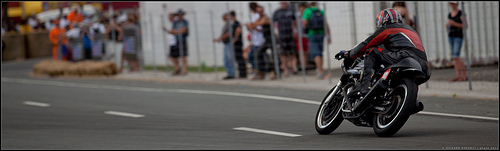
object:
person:
[85, 13, 107, 62]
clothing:
[164, 20, 196, 47]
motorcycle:
[308, 50, 433, 138]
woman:
[85, 16, 110, 62]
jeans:
[445, 35, 465, 58]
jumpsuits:
[46, 27, 69, 59]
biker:
[333, 8, 435, 98]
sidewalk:
[114, 59, 499, 100]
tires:
[366, 75, 421, 138]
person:
[243, 2, 284, 82]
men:
[113, 11, 147, 75]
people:
[158, 7, 192, 77]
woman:
[268, 0, 300, 77]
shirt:
[440, 9, 465, 39]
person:
[243, 2, 273, 81]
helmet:
[372, 7, 405, 29]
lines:
[103, 107, 148, 119]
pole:
[456, 0, 474, 93]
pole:
[321, 1, 334, 84]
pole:
[203, 8, 219, 76]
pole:
[157, 11, 169, 73]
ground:
[0, 56, 498, 150]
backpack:
[298, 8, 330, 33]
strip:
[229, 126, 303, 139]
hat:
[166, 8, 187, 15]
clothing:
[343, 22, 458, 63]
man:
[298, 1, 336, 80]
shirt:
[297, 7, 329, 39]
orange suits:
[62, 10, 85, 29]